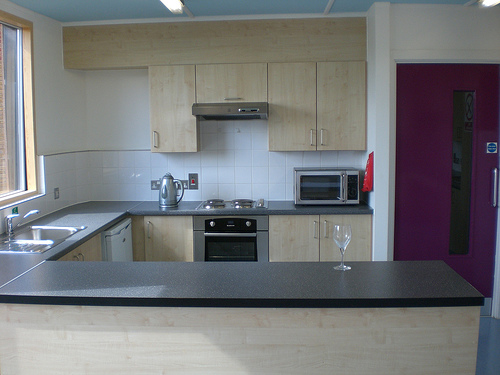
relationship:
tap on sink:
[5, 211, 21, 242] [22, 233, 65, 251]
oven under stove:
[193, 222, 270, 262] [189, 193, 276, 261]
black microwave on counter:
[293, 167, 359, 204] [87, 199, 372, 230]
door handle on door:
[490, 167, 498, 207] [392, 63, 499, 316]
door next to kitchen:
[395, 59, 500, 299] [15, 25, 466, 373]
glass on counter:
[333, 223, 352, 270] [4, 258, 486, 313]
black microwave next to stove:
[293, 167, 359, 204] [195, 191, 265, 217]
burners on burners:
[204, 197, 256, 216] [205, 199, 253, 209]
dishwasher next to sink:
[104, 215, 141, 262] [1, 218, 87, 255]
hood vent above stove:
[190, 100, 269, 117] [191, 200, 268, 259]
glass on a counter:
[327, 223, 352, 274] [78, 115, 498, 310]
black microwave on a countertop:
[293, 167, 359, 204] [12, 256, 483, 312]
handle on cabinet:
[306, 216, 318, 249] [257, 194, 317, 268]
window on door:
[450, 88, 475, 259] [395, 59, 500, 299]